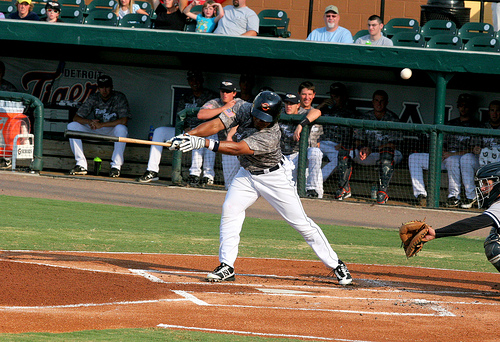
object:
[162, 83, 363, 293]
batter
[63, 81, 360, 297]
baseball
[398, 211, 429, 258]
glove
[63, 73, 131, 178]
player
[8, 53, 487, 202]
dugout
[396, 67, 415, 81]
baseball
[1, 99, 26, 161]
dispenser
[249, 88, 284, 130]
helmet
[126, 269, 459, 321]
base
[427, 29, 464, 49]
seat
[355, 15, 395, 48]
audience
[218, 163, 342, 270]
pants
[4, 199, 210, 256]
grass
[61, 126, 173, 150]
bat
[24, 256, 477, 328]
lines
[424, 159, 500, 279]
catcher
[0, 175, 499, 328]
field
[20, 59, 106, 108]
logo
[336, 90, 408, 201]
man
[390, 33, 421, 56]
chairs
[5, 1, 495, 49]
background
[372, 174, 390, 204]
shoes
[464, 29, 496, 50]
seat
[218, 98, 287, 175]
shirt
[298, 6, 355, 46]
man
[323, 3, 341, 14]
hat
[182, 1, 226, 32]
girl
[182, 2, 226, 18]
arms up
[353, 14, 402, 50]
man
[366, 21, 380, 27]
sunglasses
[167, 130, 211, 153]
hands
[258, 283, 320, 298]
home plate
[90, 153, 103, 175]
object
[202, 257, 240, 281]
right foot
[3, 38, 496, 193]
background